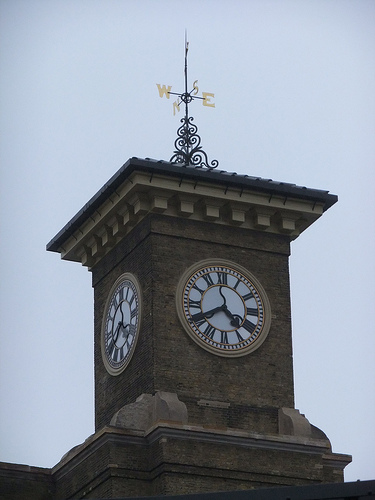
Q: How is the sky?
A: Clear.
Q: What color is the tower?
A: Brown.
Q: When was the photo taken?
A: Daytime.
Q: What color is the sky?
A: Blue.